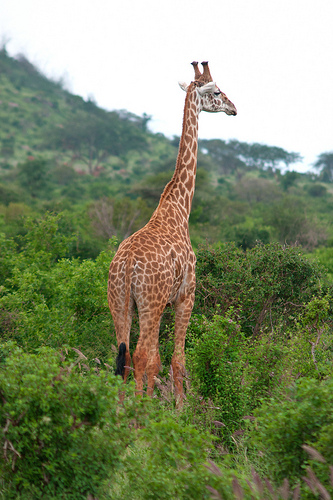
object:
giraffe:
[106, 58, 240, 421]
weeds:
[0, 304, 333, 498]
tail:
[113, 251, 134, 380]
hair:
[113, 340, 127, 380]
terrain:
[0, 48, 333, 243]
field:
[1, 189, 333, 500]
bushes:
[194, 236, 332, 341]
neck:
[153, 101, 201, 227]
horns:
[200, 60, 211, 81]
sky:
[0, 0, 332, 176]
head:
[177, 60, 239, 118]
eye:
[214, 89, 222, 96]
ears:
[196, 81, 215, 97]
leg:
[172, 274, 197, 407]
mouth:
[225, 105, 238, 118]